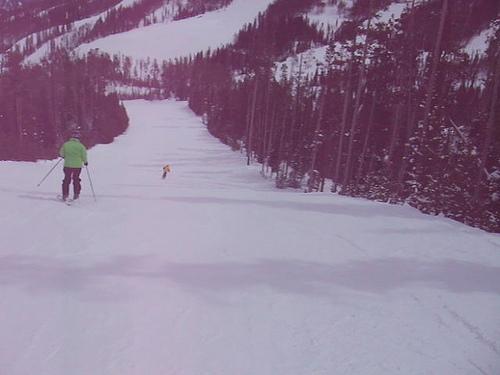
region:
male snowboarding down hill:
[35, 128, 114, 210]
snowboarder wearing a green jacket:
[48, 120, 102, 205]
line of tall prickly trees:
[200, 50, 443, 177]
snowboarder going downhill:
[156, 157, 183, 184]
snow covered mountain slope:
[103, 3, 268, 68]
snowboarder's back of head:
[71, 123, 85, 139]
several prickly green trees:
[6, 68, 116, 142]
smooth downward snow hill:
[125, 98, 270, 373]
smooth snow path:
[123, 106, 245, 373]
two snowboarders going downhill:
[34, 126, 210, 220]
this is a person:
[16, 115, 118, 210]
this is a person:
[152, 156, 180, 197]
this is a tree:
[326, 56, 355, 192]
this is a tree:
[370, 0, 428, 202]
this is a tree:
[400, 0, 465, 213]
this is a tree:
[452, 30, 499, 225]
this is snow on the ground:
[187, 246, 288, 311]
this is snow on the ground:
[58, 228, 171, 317]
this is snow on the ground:
[388, 274, 473, 355]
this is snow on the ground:
[209, 154, 271, 241]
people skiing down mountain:
[36, 95, 265, 284]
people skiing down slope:
[39, 115, 241, 275]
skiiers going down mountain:
[25, 103, 226, 250]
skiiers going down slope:
[31, 103, 223, 259]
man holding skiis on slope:
[23, 121, 131, 226]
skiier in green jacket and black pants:
[34, 123, 139, 233]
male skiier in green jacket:
[30, 115, 121, 213]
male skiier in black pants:
[36, 111, 123, 230]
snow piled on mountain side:
[170, 205, 373, 364]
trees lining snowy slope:
[217, 33, 480, 222]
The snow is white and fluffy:
[57, 234, 437, 344]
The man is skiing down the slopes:
[34, 125, 99, 210]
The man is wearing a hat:
[66, 125, 85, 140]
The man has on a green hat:
[58, 140, 91, 170]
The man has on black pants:
[59, 164, 88, 199]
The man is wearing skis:
[55, 191, 92, 209]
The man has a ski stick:
[33, 155, 67, 195]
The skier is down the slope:
[148, 156, 182, 183]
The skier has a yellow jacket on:
[159, 163, 176, 173]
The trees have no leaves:
[241, 28, 453, 192]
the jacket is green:
[57, 141, 87, 178]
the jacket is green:
[48, 130, 110, 185]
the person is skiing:
[154, 145, 208, 189]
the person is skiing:
[148, 160, 189, 182]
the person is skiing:
[38, 113, 108, 212]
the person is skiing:
[135, 135, 198, 196]